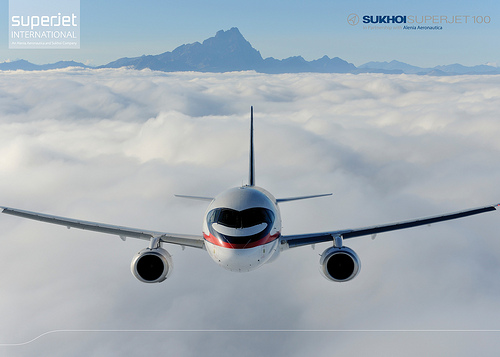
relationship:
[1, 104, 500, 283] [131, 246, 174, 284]
plane has a jet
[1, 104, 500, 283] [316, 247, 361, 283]
plane has a jet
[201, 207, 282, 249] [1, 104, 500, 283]
front of plane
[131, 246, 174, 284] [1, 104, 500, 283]
engine on airplane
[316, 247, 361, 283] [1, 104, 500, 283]
engine on airplane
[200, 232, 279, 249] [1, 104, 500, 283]
line on airplane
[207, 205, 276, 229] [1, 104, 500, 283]
windshield on airplane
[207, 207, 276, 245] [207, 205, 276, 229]
line around windshield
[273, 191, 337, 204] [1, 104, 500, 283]
tail wing at back of airplane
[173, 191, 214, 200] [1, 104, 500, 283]
tail wing at back of airplane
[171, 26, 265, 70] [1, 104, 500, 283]
tall mountain behind airplane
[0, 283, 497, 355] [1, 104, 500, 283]
several clouds under airplane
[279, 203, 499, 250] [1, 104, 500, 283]
long wing on airplane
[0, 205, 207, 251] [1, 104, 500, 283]
long wing on airplane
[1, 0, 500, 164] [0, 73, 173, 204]
sky has clouds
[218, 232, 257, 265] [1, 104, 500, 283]
nose of plane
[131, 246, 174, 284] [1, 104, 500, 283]
engine of plane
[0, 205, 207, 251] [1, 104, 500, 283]
wing of plane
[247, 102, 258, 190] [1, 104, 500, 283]
tail of plane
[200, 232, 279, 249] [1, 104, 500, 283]
stripe on front of plane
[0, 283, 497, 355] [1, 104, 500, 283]
clouds under plane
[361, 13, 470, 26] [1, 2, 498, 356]
name in top left of photo